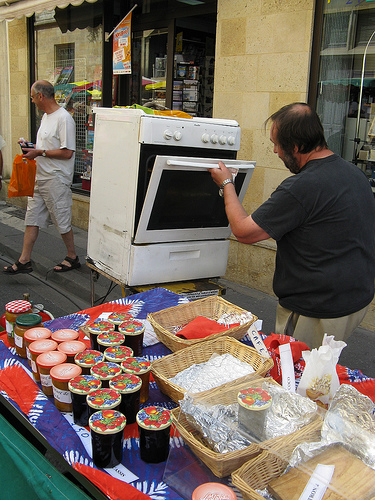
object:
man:
[206, 102, 372, 358]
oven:
[86, 104, 257, 289]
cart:
[83, 260, 226, 307]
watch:
[218, 178, 232, 198]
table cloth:
[3, 286, 374, 500]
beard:
[279, 151, 300, 174]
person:
[5, 79, 81, 274]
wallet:
[19, 140, 34, 155]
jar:
[48, 363, 82, 413]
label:
[52, 388, 72, 405]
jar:
[35, 351, 66, 398]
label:
[40, 374, 52, 387]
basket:
[146, 295, 259, 353]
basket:
[149, 336, 274, 403]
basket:
[167, 377, 322, 482]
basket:
[232, 415, 374, 500]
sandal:
[2, 260, 35, 274]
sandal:
[54, 255, 81, 271]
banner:
[110, 13, 134, 76]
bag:
[8, 153, 37, 198]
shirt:
[251, 152, 374, 319]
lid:
[136, 405, 172, 431]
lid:
[88, 410, 127, 433]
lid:
[86, 388, 121, 410]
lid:
[68, 374, 101, 394]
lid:
[109, 372, 142, 393]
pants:
[23, 171, 73, 235]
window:
[147, 168, 247, 231]